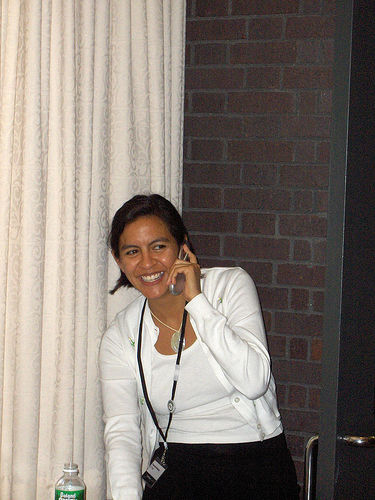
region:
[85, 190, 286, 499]
girl in a white cardigan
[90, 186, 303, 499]
girl in a white cardigan using a phone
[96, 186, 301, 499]
a woman holding a phone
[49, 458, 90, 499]
an uncapped water bottle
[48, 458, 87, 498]
a water bottle with no cap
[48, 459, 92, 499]
a water bottle witha green label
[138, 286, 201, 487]
lanyard with a name tag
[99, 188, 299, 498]
a woman smiling with her teeth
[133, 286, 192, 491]
a black lanyard with a name tag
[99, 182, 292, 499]
woman holding a silver phone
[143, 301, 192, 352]
a woman's necklace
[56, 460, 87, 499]
part of a water bottle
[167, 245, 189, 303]
part of a gray cellphone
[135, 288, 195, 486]
a black lanyard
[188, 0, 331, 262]
part of a brick wall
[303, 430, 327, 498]
a gray door handle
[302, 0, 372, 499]
part of a tall gray door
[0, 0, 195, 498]
part of a long white curtain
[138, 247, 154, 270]
the nose of a woman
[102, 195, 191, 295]
a woman's short black hair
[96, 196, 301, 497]
a woman talking on a cellphone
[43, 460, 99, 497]
an opened bottle of water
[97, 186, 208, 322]
the head of a woman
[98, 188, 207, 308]
a woman who is smiling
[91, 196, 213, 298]
a woman with a smile on her face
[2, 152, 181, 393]
a woman standing in front of a curtain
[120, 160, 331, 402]
a woman standing in front of a brick wall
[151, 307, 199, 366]
the necklace of a woman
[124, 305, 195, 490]
a black lanyard and badge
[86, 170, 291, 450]
a woman wearing a white blouse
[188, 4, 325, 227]
brick wall for structure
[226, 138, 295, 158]
individual horizontal red brick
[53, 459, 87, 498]
opened plastic bottle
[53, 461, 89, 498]
bottle without cap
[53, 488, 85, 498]
green wrapping of bottle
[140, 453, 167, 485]
identification badge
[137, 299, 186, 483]
lanyard for neck wear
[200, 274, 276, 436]
white lightweight sweater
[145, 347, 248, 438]
white undershirt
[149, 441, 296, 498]
black bottoms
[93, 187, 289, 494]
lady smiling while talking on her phone.